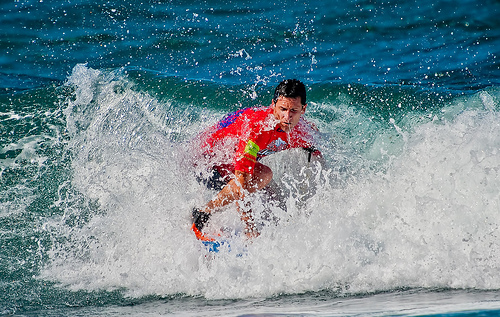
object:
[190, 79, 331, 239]
man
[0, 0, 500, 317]
water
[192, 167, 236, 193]
shorts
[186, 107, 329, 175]
shirt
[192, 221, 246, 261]
board